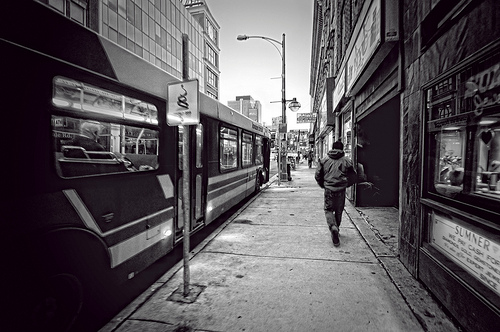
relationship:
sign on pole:
[174, 84, 191, 113] [177, 126, 194, 298]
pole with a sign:
[177, 126, 194, 298] [174, 84, 191, 113]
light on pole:
[232, 32, 251, 46] [276, 32, 291, 185]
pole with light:
[276, 32, 291, 185] [232, 32, 251, 46]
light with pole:
[232, 32, 251, 46] [276, 32, 291, 185]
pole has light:
[276, 32, 291, 185] [232, 32, 251, 46]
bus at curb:
[13, 78, 275, 315] [111, 267, 179, 329]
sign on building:
[424, 203, 499, 293] [320, 10, 498, 323]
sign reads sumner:
[424, 203, 499, 293] [452, 226, 493, 252]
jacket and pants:
[312, 148, 362, 190] [321, 187, 347, 232]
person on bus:
[72, 120, 115, 153] [13, 78, 275, 315]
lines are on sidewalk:
[198, 248, 382, 266] [153, 151, 400, 321]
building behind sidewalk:
[320, 10, 498, 323] [153, 151, 400, 321]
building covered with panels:
[72, 6, 222, 90] [102, 4, 203, 84]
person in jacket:
[314, 141, 358, 252] [312, 148, 362, 190]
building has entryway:
[320, 10, 498, 323] [357, 92, 411, 234]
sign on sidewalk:
[174, 84, 191, 113] [153, 151, 400, 321]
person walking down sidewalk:
[314, 141, 358, 252] [153, 151, 400, 321]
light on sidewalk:
[232, 32, 251, 46] [153, 151, 400, 321]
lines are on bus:
[108, 166, 284, 262] [13, 78, 275, 315]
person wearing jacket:
[314, 141, 358, 252] [312, 148, 362, 190]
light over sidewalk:
[232, 32, 251, 46] [153, 151, 400, 321]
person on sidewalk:
[314, 141, 358, 252] [153, 151, 400, 321]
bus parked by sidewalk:
[13, 78, 275, 315] [153, 151, 400, 321]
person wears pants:
[314, 141, 358, 252] [321, 187, 347, 232]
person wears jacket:
[314, 141, 358, 252] [312, 148, 362, 190]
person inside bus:
[72, 120, 115, 153] [13, 78, 275, 315]